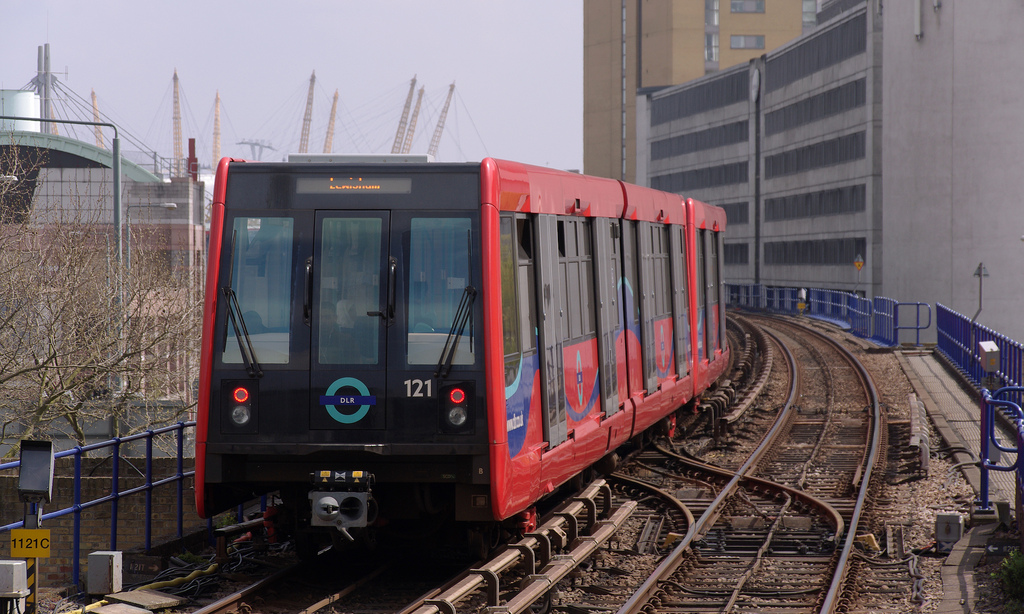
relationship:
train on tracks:
[253, 184, 733, 527] [704, 310, 858, 587]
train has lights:
[253, 184, 733, 527] [222, 375, 491, 441]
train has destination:
[253, 184, 733, 527] [317, 164, 397, 204]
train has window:
[253, 184, 733, 527] [228, 225, 296, 369]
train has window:
[253, 184, 733, 527] [313, 217, 392, 369]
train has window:
[253, 184, 733, 527] [393, 227, 478, 394]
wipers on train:
[226, 270, 481, 367] [253, 184, 733, 527]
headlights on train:
[222, 375, 491, 441] [253, 184, 733, 527]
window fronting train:
[228, 225, 296, 369] [253, 184, 733, 527]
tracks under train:
[704, 310, 858, 587] [253, 184, 733, 527]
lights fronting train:
[222, 375, 491, 441] [253, 184, 733, 527]